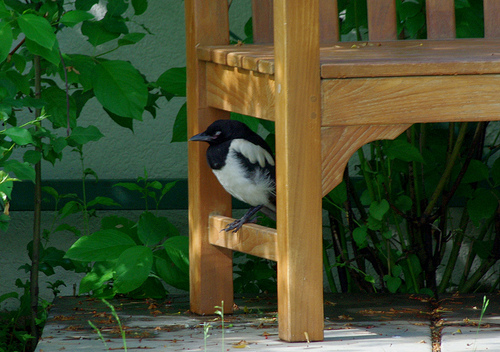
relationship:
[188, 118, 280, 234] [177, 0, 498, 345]
bird standing on bottom of bench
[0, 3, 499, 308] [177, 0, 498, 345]
green plants growing near bench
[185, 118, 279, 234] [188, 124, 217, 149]
bird with a beak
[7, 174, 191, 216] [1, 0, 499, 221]
stripe along bottom of building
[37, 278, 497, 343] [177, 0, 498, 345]
shadows on ground below bench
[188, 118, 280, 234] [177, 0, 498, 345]
bird on bench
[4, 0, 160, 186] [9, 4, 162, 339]
leaves on plant